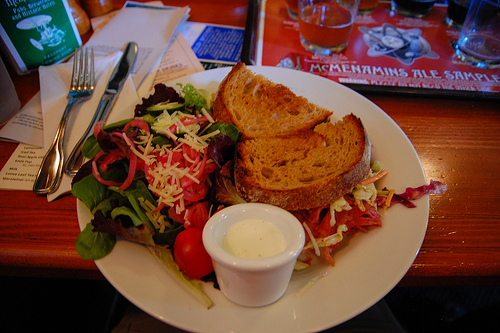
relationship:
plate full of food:
[68, 60, 442, 330] [59, 67, 444, 294]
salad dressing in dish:
[213, 216, 293, 259] [201, 204, 304, 309]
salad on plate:
[69, 78, 235, 263] [68, 60, 442, 330]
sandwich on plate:
[217, 65, 373, 225] [68, 60, 442, 330]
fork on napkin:
[30, 46, 95, 195] [32, 56, 146, 201]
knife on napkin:
[60, 41, 155, 179] [32, 56, 146, 201]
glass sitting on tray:
[450, 5, 499, 77] [232, 2, 499, 109]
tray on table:
[241, 5, 499, 95] [2, 2, 498, 276]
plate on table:
[68, 60, 442, 330] [2, 2, 498, 276]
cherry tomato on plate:
[173, 225, 218, 290] [68, 60, 442, 330]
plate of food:
[68, 60, 442, 330] [59, 67, 444, 294]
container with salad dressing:
[197, 196, 317, 317] [221, 214, 282, 266]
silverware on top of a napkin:
[35, 45, 153, 194] [26, 40, 155, 200]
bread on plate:
[234, 114, 370, 213] [68, 60, 442, 330]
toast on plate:
[218, 58, 316, 150] [99, 57, 403, 317]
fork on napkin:
[50, 43, 113, 184] [50, 43, 132, 135]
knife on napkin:
[60, 41, 155, 179] [43, 58, 141, 191]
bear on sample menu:
[293, 0, 358, 75] [253, 10, 473, 106]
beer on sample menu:
[294, 2, 360, 72] [245, 6, 436, 96]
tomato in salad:
[156, 224, 204, 273] [96, 98, 286, 283]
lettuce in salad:
[64, 207, 114, 270] [92, 99, 222, 283]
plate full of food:
[68, 60, 429, 332] [86, 71, 393, 304]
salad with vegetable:
[69, 131, 150, 259] [94, 90, 220, 275]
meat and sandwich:
[295, 189, 374, 251] [222, 73, 396, 266]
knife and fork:
[88, 40, 156, 120] [61, 36, 116, 158]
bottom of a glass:
[298, 38, 348, 71] [287, 0, 348, 61]